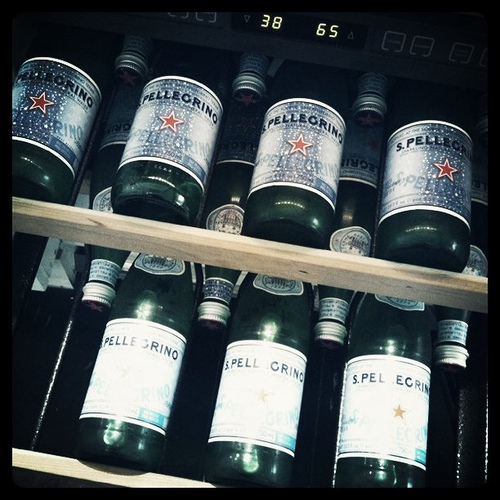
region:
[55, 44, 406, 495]
Beer in a cooler.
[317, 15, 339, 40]
The number 65 on the computer.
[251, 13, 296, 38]
The number 38 on the dash.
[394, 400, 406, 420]
A star on the bottle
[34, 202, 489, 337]
A shelf holding the bottles.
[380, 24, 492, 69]
Interactive buttons on the cooler.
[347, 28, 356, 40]
An arrow pointing upward.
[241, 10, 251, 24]
An arrow pointing downward.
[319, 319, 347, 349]
The lid to the bottle.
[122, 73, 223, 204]
The label on the bottle.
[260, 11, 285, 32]
the number thirty eight is green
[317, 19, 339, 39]
the number sixty five is green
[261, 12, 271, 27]
the number three is green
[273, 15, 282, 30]
the number eight is green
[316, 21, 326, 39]
the number six is green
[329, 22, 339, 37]
the number five is green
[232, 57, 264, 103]
the top of a wine bottle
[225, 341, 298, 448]
the label of a wine bottle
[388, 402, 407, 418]
the star is gold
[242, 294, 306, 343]
the wine bottle is dark green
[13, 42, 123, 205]
a bottle of wine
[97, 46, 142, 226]
a bottle of wine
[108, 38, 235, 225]
a bottle of wine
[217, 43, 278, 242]
a bottle of wine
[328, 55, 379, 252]
a bottle of wine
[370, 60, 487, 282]
a bottle of wine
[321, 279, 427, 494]
a bottle of wine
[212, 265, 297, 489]
a bottle of wine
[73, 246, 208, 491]
a bottle of wine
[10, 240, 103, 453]
a bottle of wine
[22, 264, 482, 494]
The bottom rack of wine bottles.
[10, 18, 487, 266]
The top rack of wine bottles.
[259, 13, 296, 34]
The number 38 on the digital display.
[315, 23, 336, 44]
The number 65 on the digital display.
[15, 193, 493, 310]
The wooden bar below the top rack of wine bottles.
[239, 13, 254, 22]
The down arrow on the display panel.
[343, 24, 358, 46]
The up arrow on the display panel.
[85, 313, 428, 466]
The white labels on the bottom rack of wine bottles.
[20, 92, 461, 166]
The red stars on the labels of the wine bottles.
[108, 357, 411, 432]
The gold stars on the labels of the wine bottles.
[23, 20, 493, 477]
Bottles of water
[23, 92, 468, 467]
The water is made by S. Pellegrino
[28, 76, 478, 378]
Some of the bottles are upside down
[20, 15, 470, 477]
The bottles are in refrigerator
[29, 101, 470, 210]
The bottles have red stars on them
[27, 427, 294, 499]
The bottles are on shelves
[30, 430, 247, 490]
The shelves are made of wood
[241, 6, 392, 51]
38 and 65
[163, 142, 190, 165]
750ml bottles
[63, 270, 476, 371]
The caps are made of aluminum